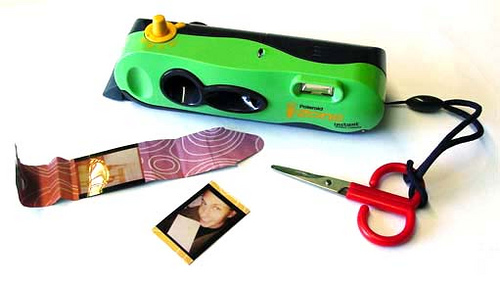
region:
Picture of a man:
[160, 190, 234, 270]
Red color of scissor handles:
[347, 150, 429, 256]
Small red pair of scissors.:
[270, 150, 439, 242]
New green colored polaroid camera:
[95, 11, 391, 141]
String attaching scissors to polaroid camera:
[398, 82, 484, 214]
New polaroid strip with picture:
[10, 122, 265, 202]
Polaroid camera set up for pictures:
[8, 12, 490, 272]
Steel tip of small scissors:
[268, 157, 356, 204]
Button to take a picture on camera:
[142, 11, 181, 42]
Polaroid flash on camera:
[289, 74, 344, 102]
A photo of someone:
[138, 180, 269, 257]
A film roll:
[3, 130, 283, 205]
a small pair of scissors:
[280, 150, 426, 253]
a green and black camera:
[118, 5, 390, 135]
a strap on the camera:
[390, 92, 491, 208]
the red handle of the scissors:
[345, 145, 435, 245]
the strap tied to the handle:
[392, 155, 438, 206]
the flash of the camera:
[301, 75, 341, 109]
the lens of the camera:
[152, 59, 202, 107]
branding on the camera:
[287, 97, 332, 114]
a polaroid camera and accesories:
[1, 5, 487, 281]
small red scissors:
[265, 153, 432, 253]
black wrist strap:
[392, 90, 492, 212]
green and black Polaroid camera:
[100, 6, 395, 137]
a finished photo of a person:
[145, 177, 256, 269]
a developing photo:
[2, 126, 262, 199]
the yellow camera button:
[140, 10, 185, 45]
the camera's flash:
[290, 72, 343, 104]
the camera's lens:
[152, 62, 267, 117]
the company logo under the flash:
[283, 96, 369, 131]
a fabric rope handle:
[408, 89, 495, 174]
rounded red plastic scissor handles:
[355, 160, 435, 270]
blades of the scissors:
[238, 161, 351, 186]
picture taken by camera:
[121, 174, 247, 274]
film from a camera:
[3, 113, 273, 216]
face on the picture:
[192, 188, 239, 245]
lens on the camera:
[138, 75, 270, 122]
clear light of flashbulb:
[278, 77, 358, 104]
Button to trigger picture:
[136, 7, 179, 57]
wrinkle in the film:
[43, 142, 75, 223]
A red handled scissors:
[271, 147, 433, 246]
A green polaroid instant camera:
[125, 16, 396, 133]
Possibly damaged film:
[53, 135, 168, 206]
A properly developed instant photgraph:
[156, 182, 249, 265]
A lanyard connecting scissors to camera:
[376, 82, 498, 184]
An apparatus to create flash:
[286, 72, 348, 104]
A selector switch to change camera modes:
[133, 14, 191, 52]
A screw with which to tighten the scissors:
[313, 167, 340, 196]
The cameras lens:
[156, 63, 278, 120]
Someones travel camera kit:
[46, 1, 475, 271]